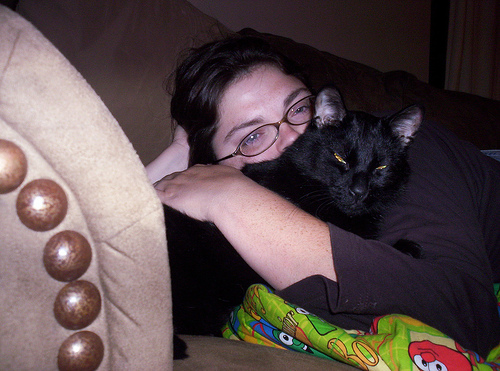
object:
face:
[286, 123, 409, 214]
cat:
[160, 88, 423, 360]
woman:
[143, 36, 500, 362]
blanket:
[221, 283, 498, 369]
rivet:
[0, 139, 27, 194]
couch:
[0, 0, 499, 369]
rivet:
[16, 178, 67, 232]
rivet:
[42, 229, 91, 282]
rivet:
[53, 279, 100, 331]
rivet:
[53, 331, 104, 371]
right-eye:
[241, 132, 266, 147]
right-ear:
[311, 80, 347, 131]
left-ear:
[385, 104, 422, 148]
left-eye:
[291, 104, 309, 117]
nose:
[349, 188, 368, 201]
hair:
[161, 23, 310, 168]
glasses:
[215, 94, 321, 165]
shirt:
[277, 124, 499, 361]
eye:
[334, 153, 346, 164]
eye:
[376, 165, 387, 170]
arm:
[212, 121, 499, 359]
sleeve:
[277, 132, 499, 359]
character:
[408, 339, 476, 370]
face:
[211, 66, 320, 171]